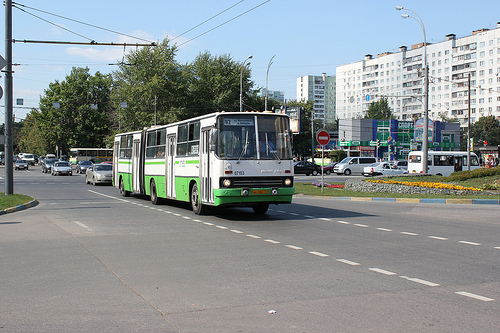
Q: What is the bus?
A: Green and white.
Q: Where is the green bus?
A: In the street.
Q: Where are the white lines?
A: On the street.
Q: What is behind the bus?
A: A car.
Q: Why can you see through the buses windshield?
A: It's clear.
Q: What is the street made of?
A: Pavement.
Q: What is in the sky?
A: Clouds.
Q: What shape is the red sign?
A: Circle.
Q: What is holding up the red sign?
A: A metal pole.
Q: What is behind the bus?
A: Building.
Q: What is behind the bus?
A: Trees.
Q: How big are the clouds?
A: Small.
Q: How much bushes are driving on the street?
A: 2.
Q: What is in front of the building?
A: Cars.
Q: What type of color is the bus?
A: Green and white.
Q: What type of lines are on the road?
A: Dashes.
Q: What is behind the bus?
A: Cars.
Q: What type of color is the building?
A: White.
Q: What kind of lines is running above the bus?
A: Power lines.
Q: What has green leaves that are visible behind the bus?
A: Trees.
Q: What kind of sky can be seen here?
A: A clear blue sky.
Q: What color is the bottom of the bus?
A: Green.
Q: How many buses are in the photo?
A: One.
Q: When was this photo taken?
A: During the day.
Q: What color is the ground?
A: Gray.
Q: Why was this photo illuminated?
A: Sunshine.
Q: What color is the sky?
A: Blue.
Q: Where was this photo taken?
A: In a city.